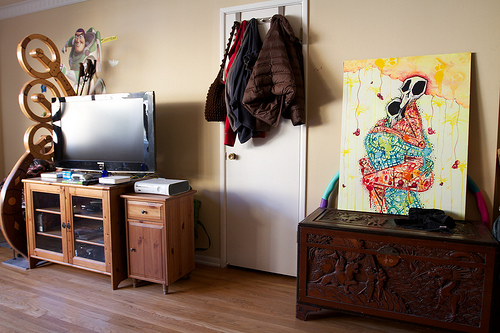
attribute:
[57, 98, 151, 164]
tv — black, flat, large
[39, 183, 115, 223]
table — brown, wood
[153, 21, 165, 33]
wall — tan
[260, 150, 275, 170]
door — white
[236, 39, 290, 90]
coats — brown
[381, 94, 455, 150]
art — abstract, colorful, artsy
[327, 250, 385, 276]
stand — brown, wooden, carved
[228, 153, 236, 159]
knob — golden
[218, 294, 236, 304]
floor — brown, wooden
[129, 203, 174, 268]
cabinet — wooden, small, brown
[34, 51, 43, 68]
statue — wood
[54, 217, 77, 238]
doors — glass